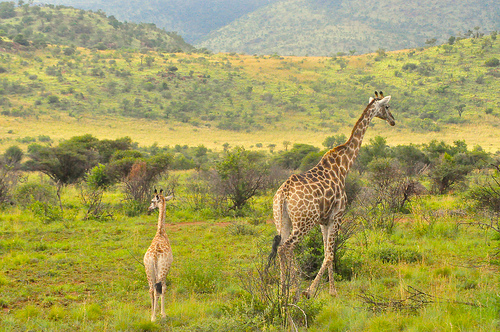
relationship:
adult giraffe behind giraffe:
[271, 89, 397, 299] [123, 180, 192, 328]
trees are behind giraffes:
[41, 51, 376, 261] [192, 86, 457, 308]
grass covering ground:
[46, 265, 122, 312] [32, 295, 79, 310]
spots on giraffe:
[306, 176, 340, 217] [248, 82, 406, 309]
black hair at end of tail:
[264, 232, 284, 272] [148, 240, 169, 297]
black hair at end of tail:
[152, 277, 164, 299] [257, 174, 297, 274]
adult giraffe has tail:
[271, 89, 397, 299] [265, 194, 287, 272]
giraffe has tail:
[143, 185, 172, 321] [151, 246, 163, 293]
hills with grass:
[2, 0, 496, 147] [0, 1, 494, 326]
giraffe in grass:
[128, 182, 186, 325] [76, 285, 249, 325]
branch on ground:
[361, 277, 483, 312] [4, 35, 497, 330]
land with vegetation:
[7, 124, 498, 329] [2, 132, 498, 330]